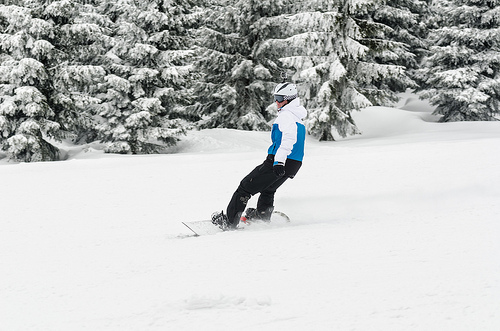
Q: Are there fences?
A: No, there are no fences.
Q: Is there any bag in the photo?
A: No, there are no bags.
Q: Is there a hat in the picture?
A: Yes, there is a hat.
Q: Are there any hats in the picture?
A: Yes, there is a hat.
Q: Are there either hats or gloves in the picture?
A: Yes, there is a hat.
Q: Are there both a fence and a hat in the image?
A: No, there is a hat but no fences.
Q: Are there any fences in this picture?
A: No, there are no fences.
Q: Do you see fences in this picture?
A: No, there are no fences.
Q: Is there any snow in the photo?
A: Yes, there is snow.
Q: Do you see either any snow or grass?
A: Yes, there is snow.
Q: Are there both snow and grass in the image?
A: No, there is snow but no grass.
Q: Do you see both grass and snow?
A: No, there is snow but no grass.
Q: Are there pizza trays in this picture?
A: No, there are no pizza trays.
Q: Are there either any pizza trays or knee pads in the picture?
A: No, there are no pizza trays or knee pads.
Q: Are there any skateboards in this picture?
A: Yes, there is a skateboard.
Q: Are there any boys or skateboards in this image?
A: Yes, there is a skateboard.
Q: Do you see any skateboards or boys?
A: Yes, there is a skateboard.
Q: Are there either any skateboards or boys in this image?
A: Yes, there is a skateboard.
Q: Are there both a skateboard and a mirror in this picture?
A: No, there is a skateboard but no mirrors.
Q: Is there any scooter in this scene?
A: No, there are no scooters.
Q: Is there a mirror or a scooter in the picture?
A: No, there are no scooters or mirrors.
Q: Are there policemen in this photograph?
A: No, there are no policemen.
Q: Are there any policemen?
A: No, there are no policemen.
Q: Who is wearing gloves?
A: The skier is wearing gloves.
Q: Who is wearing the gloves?
A: The skier is wearing gloves.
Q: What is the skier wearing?
A: The skier is wearing gloves.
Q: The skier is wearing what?
A: The skier is wearing gloves.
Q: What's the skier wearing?
A: The skier is wearing gloves.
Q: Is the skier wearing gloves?
A: Yes, the skier is wearing gloves.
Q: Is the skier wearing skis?
A: No, the skier is wearing gloves.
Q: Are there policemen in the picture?
A: No, there are no policemen.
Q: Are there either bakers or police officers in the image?
A: No, there are no police officers or bakers.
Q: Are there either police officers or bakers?
A: No, there are no police officers or bakers.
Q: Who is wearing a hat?
A: The man is wearing a hat.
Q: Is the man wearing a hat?
A: Yes, the man is wearing a hat.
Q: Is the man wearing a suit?
A: No, the man is wearing a hat.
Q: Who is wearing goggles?
A: The man is wearing goggles.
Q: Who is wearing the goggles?
A: The man is wearing goggles.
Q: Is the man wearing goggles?
A: Yes, the man is wearing goggles.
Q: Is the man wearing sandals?
A: No, the man is wearing goggles.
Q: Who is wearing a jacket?
A: The man is wearing a jacket.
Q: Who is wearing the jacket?
A: The man is wearing a jacket.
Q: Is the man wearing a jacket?
A: Yes, the man is wearing a jacket.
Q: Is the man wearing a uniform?
A: No, the man is wearing a jacket.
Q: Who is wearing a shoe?
A: The man is wearing a shoe.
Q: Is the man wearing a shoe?
A: Yes, the man is wearing a shoe.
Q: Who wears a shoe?
A: The man wears a shoe.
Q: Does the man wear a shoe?
A: Yes, the man wears a shoe.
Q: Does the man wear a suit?
A: No, the man wears a shoe.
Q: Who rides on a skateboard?
A: The man rides on a skateboard.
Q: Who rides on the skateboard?
A: The man rides on a skateboard.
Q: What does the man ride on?
A: The man rides on a skateboard.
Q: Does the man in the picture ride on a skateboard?
A: Yes, the man rides on a skateboard.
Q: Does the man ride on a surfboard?
A: No, the man rides on a skateboard.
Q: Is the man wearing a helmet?
A: No, the man is wearing a hat.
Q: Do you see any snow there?
A: Yes, there is snow.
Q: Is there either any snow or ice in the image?
A: Yes, there is snow.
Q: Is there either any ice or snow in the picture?
A: Yes, there is snow.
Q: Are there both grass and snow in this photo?
A: No, there is snow but no grass.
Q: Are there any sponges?
A: No, there are no sponges.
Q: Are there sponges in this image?
A: No, there are no sponges.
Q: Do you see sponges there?
A: No, there are no sponges.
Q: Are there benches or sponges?
A: No, there are no sponges or benches.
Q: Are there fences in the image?
A: No, there are no fences.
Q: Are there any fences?
A: No, there are no fences.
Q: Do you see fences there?
A: No, there are no fences.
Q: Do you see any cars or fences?
A: No, there are no fences or cars.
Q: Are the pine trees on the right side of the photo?
A: Yes, the pine trees are on the right of the image.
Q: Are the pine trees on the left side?
A: No, the pine trees are on the right of the image.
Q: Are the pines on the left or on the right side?
A: The pines are on the right of the image.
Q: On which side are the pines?
A: The pines are on the right of the image.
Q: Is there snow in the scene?
A: Yes, there is snow.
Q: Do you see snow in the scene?
A: Yes, there is snow.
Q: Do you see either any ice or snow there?
A: Yes, there is snow.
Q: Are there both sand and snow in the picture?
A: No, there is snow but no sand.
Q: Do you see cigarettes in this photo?
A: No, there are no cigarettes.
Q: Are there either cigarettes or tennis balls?
A: No, there are no cigarettes or tennis balls.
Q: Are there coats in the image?
A: Yes, there is a coat.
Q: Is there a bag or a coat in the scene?
A: Yes, there is a coat.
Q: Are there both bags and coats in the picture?
A: No, there is a coat but no bags.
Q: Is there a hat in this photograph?
A: Yes, there is a hat.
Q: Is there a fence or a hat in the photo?
A: Yes, there is a hat.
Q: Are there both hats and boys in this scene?
A: No, there is a hat but no boys.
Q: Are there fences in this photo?
A: No, there are no fences.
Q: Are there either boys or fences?
A: No, there are no fences or boys.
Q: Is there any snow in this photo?
A: Yes, there is snow.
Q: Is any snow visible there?
A: Yes, there is snow.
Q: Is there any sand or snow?
A: Yes, there is snow.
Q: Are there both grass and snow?
A: No, there is snow but no grass.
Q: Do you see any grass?
A: No, there is no grass.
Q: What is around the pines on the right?
A: The snow is around the pines.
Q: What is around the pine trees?
A: The snow is around the pines.